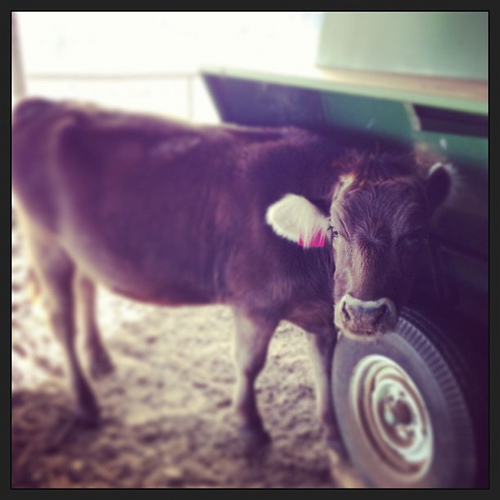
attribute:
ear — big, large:
[267, 191, 333, 249]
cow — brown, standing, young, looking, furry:
[11, 98, 455, 446]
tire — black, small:
[332, 314, 489, 489]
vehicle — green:
[202, 13, 486, 283]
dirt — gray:
[12, 236, 338, 489]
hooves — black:
[67, 392, 104, 425]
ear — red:
[424, 163, 459, 211]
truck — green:
[194, 11, 490, 495]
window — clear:
[12, 13, 320, 124]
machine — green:
[201, 13, 495, 497]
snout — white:
[330, 295, 399, 341]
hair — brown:
[13, 98, 457, 431]